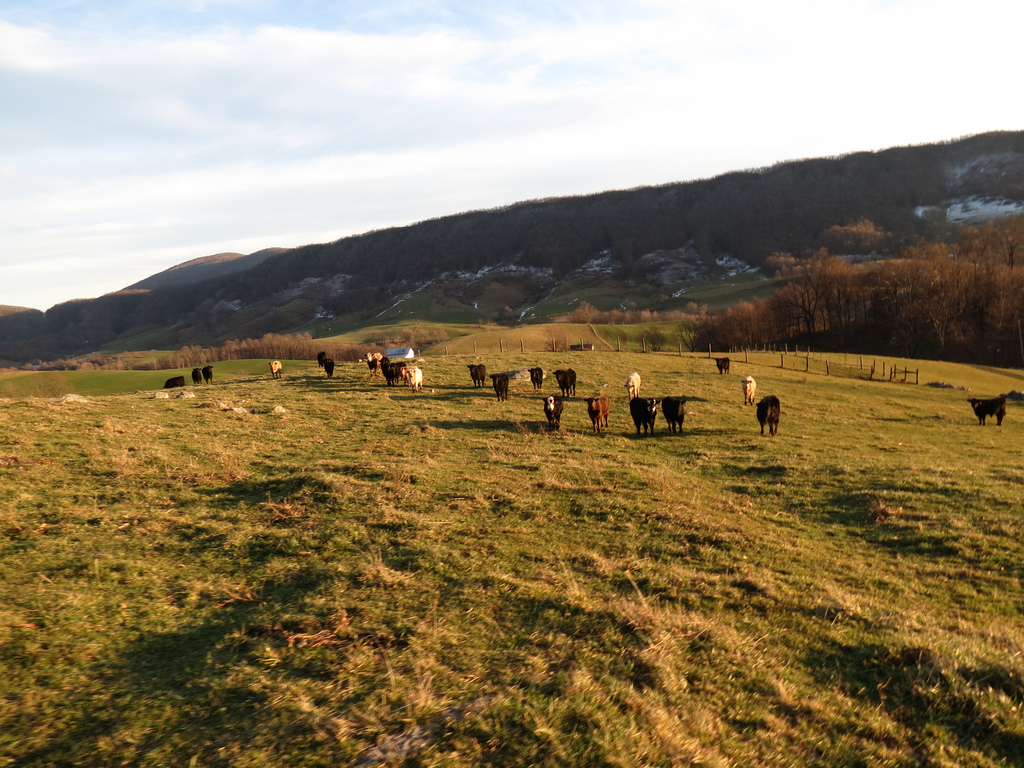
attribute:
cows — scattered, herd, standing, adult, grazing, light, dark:
[519, 367, 657, 422]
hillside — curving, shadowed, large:
[636, 349, 679, 374]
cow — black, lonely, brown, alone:
[396, 361, 433, 397]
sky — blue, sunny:
[165, 11, 194, 23]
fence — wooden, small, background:
[750, 342, 801, 372]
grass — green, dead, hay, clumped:
[261, 469, 332, 499]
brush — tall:
[229, 333, 255, 366]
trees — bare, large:
[409, 294, 463, 323]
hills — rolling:
[347, 209, 443, 326]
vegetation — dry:
[430, 298, 497, 337]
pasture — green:
[301, 394, 362, 420]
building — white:
[378, 336, 412, 354]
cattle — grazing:
[375, 357, 424, 391]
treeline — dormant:
[488, 296, 525, 328]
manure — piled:
[541, 434, 570, 452]